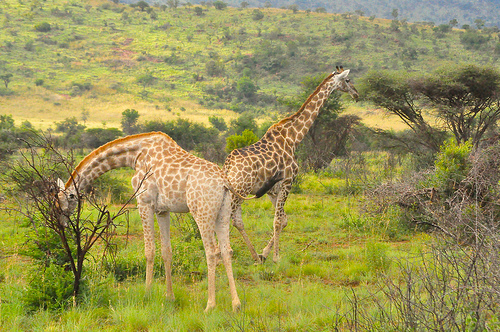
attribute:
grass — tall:
[244, 282, 319, 329]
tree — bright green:
[120, 105, 139, 133]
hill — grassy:
[2, 2, 498, 112]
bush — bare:
[0, 129, 152, 303]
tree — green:
[363, 60, 498, 146]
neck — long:
[294, 78, 336, 136]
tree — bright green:
[161, 48, 197, 76]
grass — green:
[5, 134, 498, 323]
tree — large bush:
[347, 62, 499, 144]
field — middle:
[11, 172, 498, 328]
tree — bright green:
[135, 69, 154, 91]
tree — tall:
[343, 53, 498, 173]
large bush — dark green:
[359, 62, 497, 150]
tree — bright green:
[193, 55, 230, 87]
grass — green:
[281, 264, 378, 307]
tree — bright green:
[34, 78, 43, 86]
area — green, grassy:
[5, 157, 485, 320]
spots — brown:
[239, 100, 318, 181]